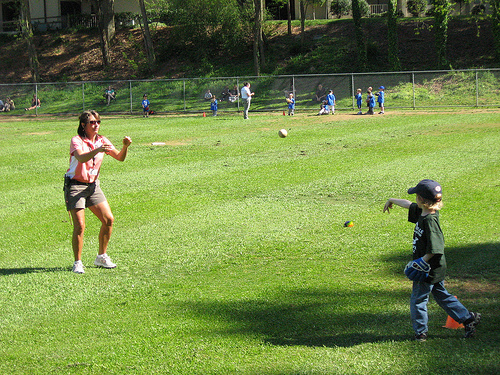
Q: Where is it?
A: This is at the park.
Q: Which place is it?
A: It is a park.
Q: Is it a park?
A: Yes, it is a park.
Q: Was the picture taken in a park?
A: Yes, it was taken in a park.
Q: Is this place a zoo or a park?
A: It is a park.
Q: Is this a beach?
A: No, it is a park.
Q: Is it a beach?
A: No, it is a park.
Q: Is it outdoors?
A: Yes, it is outdoors.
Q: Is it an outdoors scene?
A: Yes, it is outdoors.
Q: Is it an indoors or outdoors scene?
A: It is outdoors.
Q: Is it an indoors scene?
A: No, it is outdoors.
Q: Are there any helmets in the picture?
A: No, there are no helmets.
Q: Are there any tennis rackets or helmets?
A: No, there are no helmets or tennis rackets.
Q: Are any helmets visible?
A: No, there are no helmets.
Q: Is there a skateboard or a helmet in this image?
A: No, there are no helmets or skateboards.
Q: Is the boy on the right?
A: Yes, the boy is on the right of the image.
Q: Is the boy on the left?
A: No, the boy is on the right of the image.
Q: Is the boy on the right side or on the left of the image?
A: The boy is on the right of the image.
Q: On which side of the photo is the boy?
A: The boy is on the right of the image.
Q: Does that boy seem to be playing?
A: Yes, the boy is playing.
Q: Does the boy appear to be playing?
A: Yes, the boy is playing.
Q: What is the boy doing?
A: The boy is playing.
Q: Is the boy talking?
A: No, the boy is playing.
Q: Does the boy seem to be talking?
A: No, the boy is playing.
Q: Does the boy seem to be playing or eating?
A: The boy is playing.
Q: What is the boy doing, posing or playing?
A: The boy is playing.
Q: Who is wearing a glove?
A: The boy is wearing a glove.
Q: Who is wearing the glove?
A: The boy is wearing a glove.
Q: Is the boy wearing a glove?
A: Yes, the boy is wearing a glove.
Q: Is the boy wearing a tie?
A: No, the boy is wearing a glove.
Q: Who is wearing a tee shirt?
A: The boy is wearing a tee shirt.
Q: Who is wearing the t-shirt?
A: The boy is wearing a tee shirt.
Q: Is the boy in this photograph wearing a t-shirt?
A: Yes, the boy is wearing a t-shirt.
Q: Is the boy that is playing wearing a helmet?
A: No, the boy is wearing a t-shirt.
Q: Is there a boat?
A: No, there are no boats.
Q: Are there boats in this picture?
A: No, there are no boats.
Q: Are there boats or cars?
A: No, there are no boats or cars.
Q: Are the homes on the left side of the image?
A: Yes, the homes are on the left of the image.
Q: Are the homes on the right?
A: No, the homes are on the left of the image.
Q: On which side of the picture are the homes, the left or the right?
A: The homes are on the left of the image.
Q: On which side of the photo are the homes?
A: The homes are on the left of the image.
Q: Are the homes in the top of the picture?
A: Yes, the homes are in the top of the image.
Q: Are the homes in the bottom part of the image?
A: No, the homes are in the top of the image.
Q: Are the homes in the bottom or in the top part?
A: The homes are in the top of the image.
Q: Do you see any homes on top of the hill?
A: Yes, there are homes on top of the hill.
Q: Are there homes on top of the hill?
A: Yes, there are homes on top of the hill.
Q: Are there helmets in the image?
A: No, there are no helmets.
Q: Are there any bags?
A: No, there are no bags.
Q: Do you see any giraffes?
A: No, there are no giraffes.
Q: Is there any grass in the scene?
A: Yes, there is grass.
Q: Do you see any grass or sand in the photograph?
A: Yes, there is grass.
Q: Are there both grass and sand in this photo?
A: No, there is grass but no sand.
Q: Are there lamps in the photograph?
A: No, there are no lamps.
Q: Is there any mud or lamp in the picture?
A: No, there are no lamps or mud.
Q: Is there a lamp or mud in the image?
A: No, there are no lamps or mud.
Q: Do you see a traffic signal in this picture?
A: No, there are no traffic lights.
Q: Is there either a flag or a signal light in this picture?
A: No, there are no traffic lights or flags.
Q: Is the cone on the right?
A: Yes, the cone is on the right of the image.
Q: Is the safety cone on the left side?
A: No, the safety cone is on the right of the image.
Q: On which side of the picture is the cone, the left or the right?
A: The cone is on the right of the image.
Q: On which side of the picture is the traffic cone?
A: The traffic cone is on the right of the image.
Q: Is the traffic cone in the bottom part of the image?
A: Yes, the traffic cone is in the bottom of the image.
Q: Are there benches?
A: No, there are no benches.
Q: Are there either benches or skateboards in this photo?
A: No, there are no benches or skateboards.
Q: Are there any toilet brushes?
A: No, there are no toilet brushes.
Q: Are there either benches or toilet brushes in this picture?
A: No, there are no toilet brushes or benches.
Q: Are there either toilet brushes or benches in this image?
A: No, there are no toilet brushes or benches.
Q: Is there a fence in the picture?
A: Yes, there is a fence.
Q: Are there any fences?
A: Yes, there is a fence.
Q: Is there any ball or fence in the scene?
A: Yes, there is a fence.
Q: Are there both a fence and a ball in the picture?
A: Yes, there are both a fence and a ball.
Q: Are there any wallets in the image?
A: No, there are no wallets.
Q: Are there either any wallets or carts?
A: No, there are no wallets or carts.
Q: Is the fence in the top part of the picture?
A: Yes, the fence is in the top of the image.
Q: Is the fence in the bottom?
A: No, the fence is in the top of the image.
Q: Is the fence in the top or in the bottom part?
A: The fence is in the top of the image.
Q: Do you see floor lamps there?
A: No, there are no floor lamps.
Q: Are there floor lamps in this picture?
A: No, there are no floor lamps.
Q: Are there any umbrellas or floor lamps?
A: No, there are no floor lamps or umbrellas.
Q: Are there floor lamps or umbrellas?
A: No, there are no floor lamps or umbrellas.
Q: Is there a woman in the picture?
A: Yes, there is a woman.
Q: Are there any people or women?
A: Yes, there is a woman.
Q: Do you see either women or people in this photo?
A: Yes, there is a woman.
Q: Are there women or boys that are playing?
A: Yes, the woman is playing.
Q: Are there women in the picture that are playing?
A: Yes, there is a woman that is playing.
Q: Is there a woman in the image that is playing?
A: Yes, there is a woman that is playing.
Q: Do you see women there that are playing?
A: Yes, there is a woman that is playing.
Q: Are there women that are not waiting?
A: Yes, there is a woman that is playing.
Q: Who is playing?
A: The woman is playing.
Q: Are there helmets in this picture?
A: No, there are no helmets.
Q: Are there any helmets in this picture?
A: No, there are no helmets.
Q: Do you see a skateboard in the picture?
A: No, there are no skateboards.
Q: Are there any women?
A: Yes, there is a woman.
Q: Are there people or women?
A: Yes, there is a woman.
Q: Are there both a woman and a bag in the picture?
A: No, there is a woman but no bags.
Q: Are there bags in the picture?
A: No, there are no bags.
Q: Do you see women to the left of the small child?
A: Yes, there is a woman to the left of the kid.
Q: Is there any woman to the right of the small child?
A: No, the woman is to the left of the child.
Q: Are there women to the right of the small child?
A: No, the woman is to the left of the child.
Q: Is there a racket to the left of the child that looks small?
A: No, there is a woman to the left of the child.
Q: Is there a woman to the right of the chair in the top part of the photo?
A: Yes, there is a woman to the right of the chair.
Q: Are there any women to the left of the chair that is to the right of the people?
A: No, the woman is to the right of the chair.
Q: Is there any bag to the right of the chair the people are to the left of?
A: No, there is a woman to the right of the chair.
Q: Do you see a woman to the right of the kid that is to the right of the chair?
A: Yes, there is a woman to the right of the kid.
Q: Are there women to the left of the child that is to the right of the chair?
A: No, the woman is to the right of the kid.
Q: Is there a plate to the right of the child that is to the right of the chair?
A: No, there is a woman to the right of the kid.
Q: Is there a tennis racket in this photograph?
A: No, there are no rackets.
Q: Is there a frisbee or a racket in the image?
A: No, there are no rackets or frisbees.